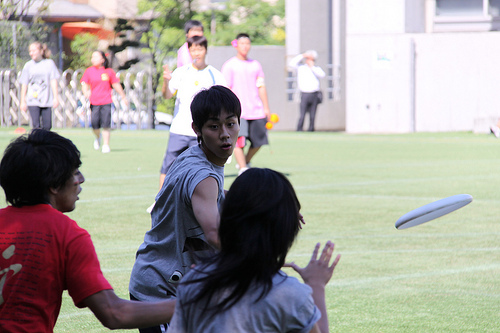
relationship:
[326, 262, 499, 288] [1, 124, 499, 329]
boundary line on ground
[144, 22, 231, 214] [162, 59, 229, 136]
man has white shirt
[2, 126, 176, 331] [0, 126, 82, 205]
man has hair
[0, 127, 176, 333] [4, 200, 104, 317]
man has red shirt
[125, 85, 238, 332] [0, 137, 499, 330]
woman walking on field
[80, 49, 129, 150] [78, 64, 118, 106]
woman in red shirt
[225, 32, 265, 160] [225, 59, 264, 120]
man in shirt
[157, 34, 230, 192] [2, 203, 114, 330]
man in red shirt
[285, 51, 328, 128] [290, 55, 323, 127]
man in uniform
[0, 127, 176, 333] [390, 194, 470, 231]
man playing frisbee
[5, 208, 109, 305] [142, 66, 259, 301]
back of man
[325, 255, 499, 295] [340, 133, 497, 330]
boundary line painted on field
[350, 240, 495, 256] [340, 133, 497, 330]
boundary line painted on field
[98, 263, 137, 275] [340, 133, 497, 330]
boundary line painted on field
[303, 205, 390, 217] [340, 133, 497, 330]
boundary line painted on field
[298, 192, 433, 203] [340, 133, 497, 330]
boundary line painted on field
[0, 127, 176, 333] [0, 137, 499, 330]
man gathered in field